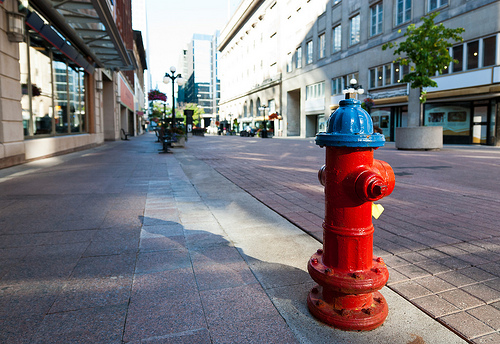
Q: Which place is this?
A: It is a city.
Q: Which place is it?
A: It is a city.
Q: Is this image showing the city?
A: Yes, it is showing the city.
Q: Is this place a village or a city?
A: It is a city.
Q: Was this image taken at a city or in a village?
A: It was taken at a city.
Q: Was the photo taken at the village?
A: No, the picture was taken in the city.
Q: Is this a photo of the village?
A: No, the picture is showing the city.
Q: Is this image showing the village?
A: No, the picture is showing the city.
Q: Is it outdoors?
A: Yes, it is outdoors.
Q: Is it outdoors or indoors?
A: It is outdoors.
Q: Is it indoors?
A: No, it is outdoors.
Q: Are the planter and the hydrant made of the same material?
A: No, the planter is made of concrete and the hydrant is made of metal.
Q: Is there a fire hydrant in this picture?
A: Yes, there is a fire hydrant.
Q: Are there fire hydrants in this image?
A: Yes, there is a fire hydrant.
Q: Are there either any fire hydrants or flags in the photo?
A: Yes, there is a fire hydrant.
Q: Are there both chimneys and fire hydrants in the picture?
A: No, there is a fire hydrant but no chimneys.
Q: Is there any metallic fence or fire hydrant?
A: Yes, there is a metal fire hydrant.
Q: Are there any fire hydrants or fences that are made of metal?
A: Yes, the fire hydrant is made of metal.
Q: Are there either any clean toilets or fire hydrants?
A: Yes, there is a clean fire hydrant.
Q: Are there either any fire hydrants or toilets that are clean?
A: Yes, the fire hydrant is clean.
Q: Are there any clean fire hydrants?
A: Yes, there is a clean fire hydrant.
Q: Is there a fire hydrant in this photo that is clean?
A: Yes, there is a fire hydrant that is clean.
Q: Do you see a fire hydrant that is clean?
A: Yes, there is a fire hydrant that is clean.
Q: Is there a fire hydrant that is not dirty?
A: Yes, there is a clean fire hydrant.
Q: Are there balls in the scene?
A: No, there are no balls.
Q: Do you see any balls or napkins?
A: No, there are no balls or napkins.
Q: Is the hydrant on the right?
A: Yes, the hydrant is on the right of the image.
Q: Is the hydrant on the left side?
A: No, the hydrant is on the right of the image.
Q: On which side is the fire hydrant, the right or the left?
A: The fire hydrant is on the right of the image.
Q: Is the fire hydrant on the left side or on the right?
A: The fire hydrant is on the right of the image.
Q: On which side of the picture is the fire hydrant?
A: The fire hydrant is on the right of the image.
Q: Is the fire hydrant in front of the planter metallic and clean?
A: Yes, the hydrant is metallic and clean.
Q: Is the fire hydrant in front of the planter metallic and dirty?
A: No, the hydrant is metallic but clean.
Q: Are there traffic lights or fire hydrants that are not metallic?
A: No, there is a fire hydrant but it is metallic.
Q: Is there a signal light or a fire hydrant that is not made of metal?
A: No, there is a fire hydrant but it is made of metal.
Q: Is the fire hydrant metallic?
A: Yes, the fire hydrant is metallic.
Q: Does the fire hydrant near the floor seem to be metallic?
A: Yes, the hydrant is metallic.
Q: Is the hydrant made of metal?
A: Yes, the hydrant is made of metal.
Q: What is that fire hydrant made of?
A: The fire hydrant is made of metal.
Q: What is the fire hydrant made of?
A: The fire hydrant is made of metal.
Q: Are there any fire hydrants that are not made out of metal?
A: No, there is a fire hydrant but it is made of metal.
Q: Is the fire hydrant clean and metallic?
A: Yes, the fire hydrant is clean and metallic.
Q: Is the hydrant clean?
A: Yes, the hydrant is clean.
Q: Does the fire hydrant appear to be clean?
A: Yes, the fire hydrant is clean.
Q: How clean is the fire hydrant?
A: The fire hydrant is clean.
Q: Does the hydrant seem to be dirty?
A: No, the hydrant is clean.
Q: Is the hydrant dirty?
A: No, the hydrant is clean.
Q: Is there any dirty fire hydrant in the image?
A: No, there is a fire hydrant but it is clean.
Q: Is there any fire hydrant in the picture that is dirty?
A: No, there is a fire hydrant but it is clean.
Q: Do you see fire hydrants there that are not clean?
A: No, there is a fire hydrant but it is clean.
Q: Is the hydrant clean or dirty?
A: The hydrant is clean.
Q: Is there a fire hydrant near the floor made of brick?
A: Yes, there is a fire hydrant near the floor.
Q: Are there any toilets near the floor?
A: No, there is a fire hydrant near the floor.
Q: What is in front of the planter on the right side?
A: The hydrant is in front of the planter.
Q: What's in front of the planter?
A: The hydrant is in front of the planter.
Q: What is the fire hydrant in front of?
A: The fire hydrant is in front of the planter.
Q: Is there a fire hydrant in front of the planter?
A: Yes, there is a fire hydrant in front of the planter.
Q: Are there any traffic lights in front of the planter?
A: No, there is a fire hydrant in front of the planter.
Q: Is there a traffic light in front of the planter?
A: No, there is a fire hydrant in front of the planter.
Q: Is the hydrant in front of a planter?
A: Yes, the hydrant is in front of a planter.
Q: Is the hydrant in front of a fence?
A: No, the hydrant is in front of a planter.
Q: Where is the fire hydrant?
A: The fire hydrant is on the sidewalk.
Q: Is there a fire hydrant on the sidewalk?
A: Yes, there is a fire hydrant on the sidewalk.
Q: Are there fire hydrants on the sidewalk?
A: Yes, there is a fire hydrant on the sidewalk.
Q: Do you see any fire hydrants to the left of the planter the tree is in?
A: Yes, there is a fire hydrant to the left of the planter.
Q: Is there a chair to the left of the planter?
A: No, there is a fire hydrant to the left of the planter.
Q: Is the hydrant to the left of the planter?
A: Yes, the hydrant is to the left of the planter.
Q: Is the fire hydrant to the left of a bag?
A: No, the fire hydrant is to the left of the planter.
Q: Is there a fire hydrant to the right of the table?
A: Yes, there is a fire hydrant to the right of the table.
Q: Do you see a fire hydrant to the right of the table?
A: Yes, there is a fire hydrant to the right of the table.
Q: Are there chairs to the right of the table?
A: No, there is a fire hydrant to the right of the table.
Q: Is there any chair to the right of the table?
A: No, there is a fire hydrant to the right of the table.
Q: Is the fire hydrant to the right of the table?
A: Yes, the fire hydrant is to the right of the table.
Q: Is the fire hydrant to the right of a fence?
A: No, the fire hydrant is to the right of the table.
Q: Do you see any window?
A: Yes, there is a window.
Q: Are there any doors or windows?
A: Yes, there is a window.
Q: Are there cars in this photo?
A: No, there are no cars.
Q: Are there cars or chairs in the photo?
A: No, there are no cars or chairs.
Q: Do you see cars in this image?
A: No, there are no cars.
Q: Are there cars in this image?
A: No, there are no cars.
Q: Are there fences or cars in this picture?
A: No, there are no cars or fences.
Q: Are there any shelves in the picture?
A: No, there are no shelves.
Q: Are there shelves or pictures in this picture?
A: No, there are no shelves or pictures.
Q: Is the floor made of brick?
A: Yes, the floor is made of brick.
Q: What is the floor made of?
A: The floor is made of brick.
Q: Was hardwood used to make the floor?
A: No, the floor is made of brick.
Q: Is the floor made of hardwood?
A: No, the floor is made of brick.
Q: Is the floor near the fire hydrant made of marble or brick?
A: The floor is made of brick.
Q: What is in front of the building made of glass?
A: The floor is in front of the building.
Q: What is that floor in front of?
A: The floor is in front of the building.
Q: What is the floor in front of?
A: The floor is in front of the building.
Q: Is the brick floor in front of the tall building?
A: Yes, the floor is in front of the building.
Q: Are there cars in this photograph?
A: No, there are no cars.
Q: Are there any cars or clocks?
A: No, there are no cars or clocks.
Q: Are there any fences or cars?
A: No, there are no cars or fences.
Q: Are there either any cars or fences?
A: No, there are no cars or fences.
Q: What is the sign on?
A: The sign is on the building.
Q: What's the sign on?
A: The sign is on the building.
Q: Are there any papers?
A: No, there are no papers.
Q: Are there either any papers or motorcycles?
A: No, there are no papers or motorcycles.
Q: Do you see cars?
A: No, there are no cars.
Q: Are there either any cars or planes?
A: No, there are no cars or planes.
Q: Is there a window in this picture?
A: Yes, there are windows.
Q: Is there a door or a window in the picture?
A: Yes, there are windows.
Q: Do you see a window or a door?
A: Yes, there are windows.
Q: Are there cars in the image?
A: No, there are no cars.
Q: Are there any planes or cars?
A: No, there are no cars or planes.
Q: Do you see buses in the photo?
A: No, there are no buses.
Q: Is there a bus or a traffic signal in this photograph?
A: No, there are no buses or traffic lights.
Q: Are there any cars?
A: No, there are no cars.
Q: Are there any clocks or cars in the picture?
A: No, there are no cars or clocks.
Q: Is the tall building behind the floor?
A: Yes, the building is behind the floor.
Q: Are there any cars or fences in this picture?
A: No, there are no cars or fences.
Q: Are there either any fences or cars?
A: No, there are no cars or fences.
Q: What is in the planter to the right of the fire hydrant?
A: The tree is in the planter.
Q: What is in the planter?
A: The tree is in the planter.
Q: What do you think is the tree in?
A: The tree is in the planter.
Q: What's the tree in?
A: The tree is in the planter.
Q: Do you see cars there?
A: No, there are no cars.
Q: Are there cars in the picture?
A: No, there are no cars.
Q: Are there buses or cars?
A: No, there are no cars or buses.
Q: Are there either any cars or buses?
A: No, there are no cars or buses.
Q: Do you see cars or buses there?
A: No, there are no cars or buses.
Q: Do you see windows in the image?
A: Yes, there are windows.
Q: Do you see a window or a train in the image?
A: Yes, there are windows.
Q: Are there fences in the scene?
A: No, there are no fences.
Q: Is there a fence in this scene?
A: No, there are no fences.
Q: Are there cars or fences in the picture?
A: No, there are no fences or cars.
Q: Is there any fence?
A: No, there are no fences.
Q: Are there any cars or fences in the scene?
A: No, there are no fences or cars.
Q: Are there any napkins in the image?
A: No, there are no napkins.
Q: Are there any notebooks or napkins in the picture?
A: No, there are no napkins or notebooks.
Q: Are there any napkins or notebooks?
A: No, there are no napkins or notebooks.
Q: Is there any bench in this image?
A: Yes, there is a bench.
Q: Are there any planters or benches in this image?
A: Yes, there is a bench.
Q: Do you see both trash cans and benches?
A: No, there is a bench but no trash cans.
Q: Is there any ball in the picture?
A: No, there are no balls.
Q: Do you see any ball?
A: No, there are no balls.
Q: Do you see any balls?
A: No, there are no balls.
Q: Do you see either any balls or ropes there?
A: No, there are no balls or ropes.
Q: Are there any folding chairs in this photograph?
A: No, there are no folding chairs.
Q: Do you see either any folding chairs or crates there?
A: No, there are no folding chairs or crates.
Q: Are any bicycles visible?
A: No, there are no bicycles.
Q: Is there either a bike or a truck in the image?
A: No, there are no bikes or trucks.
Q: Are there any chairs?
A: No, there are no chairs.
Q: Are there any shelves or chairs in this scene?
A: No, there are no chairs or shelves.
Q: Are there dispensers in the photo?
A: No, there are no dispensers.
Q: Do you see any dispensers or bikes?
A: No, there are no dispensers or bikes.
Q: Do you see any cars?
A: No, there are no cars.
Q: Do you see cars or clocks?
A: No, there are no cars or clocks.